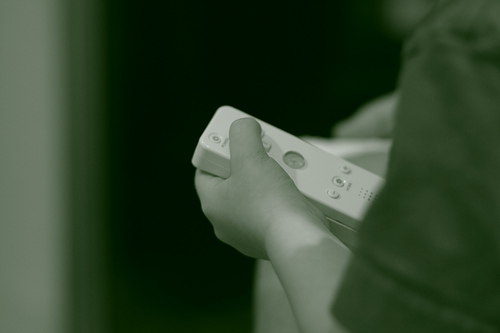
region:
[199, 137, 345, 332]
THAT IS A HAND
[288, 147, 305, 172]
THAT IS A BUTTON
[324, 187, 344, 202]
THAT IS A BUTTON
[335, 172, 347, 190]
THAT IS A BUTTON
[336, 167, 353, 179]
THAT IS A BUTTON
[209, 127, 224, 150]
THAT IS A BUTTON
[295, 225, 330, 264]
part of a wrist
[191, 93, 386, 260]
White video game controller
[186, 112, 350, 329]
Hand holding the video game controller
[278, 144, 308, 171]
Clear circle button on controller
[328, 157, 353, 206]
A row of three buttons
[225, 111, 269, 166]
Thumb of hand on the controller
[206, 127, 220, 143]
Small circular button at the top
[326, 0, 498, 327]
Black shirt on the person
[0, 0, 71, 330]
White wall in the back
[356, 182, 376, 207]
Small holes in the controller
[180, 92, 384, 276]
A hand and a controller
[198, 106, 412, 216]
white Nintendo Wii controller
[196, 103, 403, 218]
small white controller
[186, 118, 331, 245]
small hand holding controller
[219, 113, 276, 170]
thumb on a small hand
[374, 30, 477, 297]
dark colored shirt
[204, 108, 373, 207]
buttons on a controller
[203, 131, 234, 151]
power button on white stick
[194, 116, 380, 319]
arm on a small person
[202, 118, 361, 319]
wrist on a small person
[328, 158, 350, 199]
three small buttons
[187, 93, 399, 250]
The person has a Wii in his hand.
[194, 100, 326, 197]
The Wii is white.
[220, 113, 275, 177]
The person is pressing a button on the Wii.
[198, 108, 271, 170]
The finger is next to the power button.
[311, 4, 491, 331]
The person is wearing a short sleeve shirt.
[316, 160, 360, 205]
Three buttons are next to each other.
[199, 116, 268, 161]
The power button is next to the thumb.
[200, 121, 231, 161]
The power button is round.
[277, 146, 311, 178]
The button is big.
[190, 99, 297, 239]
The thumb is the only finger visible.